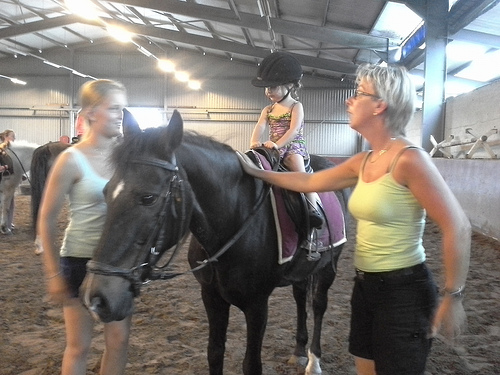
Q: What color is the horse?
A: Black.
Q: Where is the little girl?
A: On the horse.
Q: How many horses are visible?
A: Two.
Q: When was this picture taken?
A: In daytime.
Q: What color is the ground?
A: Brown.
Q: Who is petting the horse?
A: The older lady.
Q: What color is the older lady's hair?
A: Gray and white.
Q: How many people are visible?
A: Four.